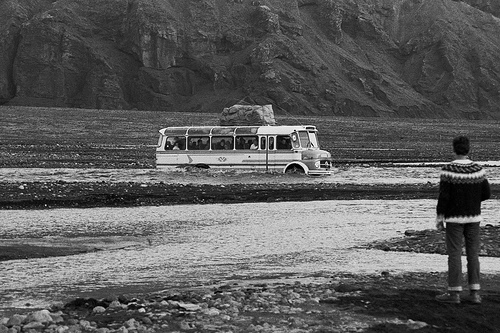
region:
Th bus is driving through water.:
[84, 81, 394, 231]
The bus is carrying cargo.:
[160, 94, 325, 136]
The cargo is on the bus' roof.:
[154, 97, 316, 136]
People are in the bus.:
[155, 127, 288, 155]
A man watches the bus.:
[418, 117, 498, 314]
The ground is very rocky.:
[0, 267, 379, 331]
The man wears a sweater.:
[427, 151, 497, 232]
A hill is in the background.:
[0, 0, 497, 124]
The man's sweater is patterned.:
[425, 151, 496, 235]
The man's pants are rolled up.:
[437, 265, 486, 301]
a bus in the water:
[107, 45, 356, 210]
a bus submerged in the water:
[82, 13, 407, 239]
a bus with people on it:
[89, 60, 410, 237]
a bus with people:
[85, 93, 358, 196]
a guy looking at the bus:
[103, 30, 489, 327]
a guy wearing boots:
[382, 66, 499, 301]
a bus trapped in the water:
[129, 20, 433, 292]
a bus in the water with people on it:
[94, 67, 431, 289]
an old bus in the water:
[103, 85, 365, 220]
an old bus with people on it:
[111, 80, 421, 237]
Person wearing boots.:
[428, 284, 497, 306]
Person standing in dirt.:
[397, 271, 491, 328]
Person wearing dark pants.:
[447, 221, 482, 298]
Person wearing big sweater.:
[437, 193, 480, 232]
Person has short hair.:
[447, 128, 462, 153]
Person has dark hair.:
[443, 134, 468, 170]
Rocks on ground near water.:
[152, 164, 395, 325]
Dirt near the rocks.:
[303, 262, 380, 325]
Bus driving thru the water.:
[168, 96, 381, 228]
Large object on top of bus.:
[212, 99, 304, 160]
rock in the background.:
[92, 22, 212, 65]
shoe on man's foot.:
[436, 291, 464, 313]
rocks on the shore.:
[180, 295, 260, 319]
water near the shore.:
[225, 206, 312, 256]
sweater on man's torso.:
[437, 176, 483, 221]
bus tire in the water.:
[287, 164, 302, 176]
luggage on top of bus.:
[225, 102, 271, 120]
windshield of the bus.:
[301, 131, 314, 144]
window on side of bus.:
[213, 140, 230, 145]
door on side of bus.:
[260, 135, 273, 166]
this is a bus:
[148, 105, 330, 177]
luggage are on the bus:
[221, 97, 271, 123]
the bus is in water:
[143, 122, 333, 182]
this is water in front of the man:
[36, 204, 373, 262]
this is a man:
[430, 120, 495, 313]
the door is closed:
[256, 132, 273, 162]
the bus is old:
[148, 119, 330, 179]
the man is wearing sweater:
[441, 167, 480, 215]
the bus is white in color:
[163, 146, 280, 166]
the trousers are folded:
[471, 277, 484, 289]